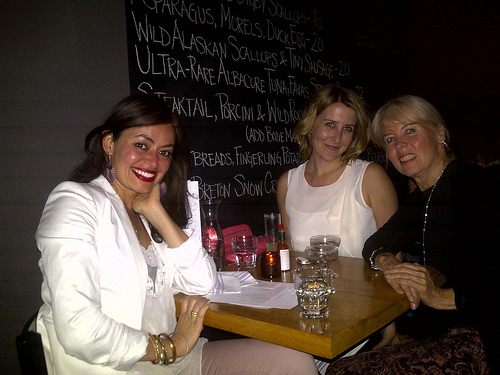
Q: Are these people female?
A: Yes, all the people are female.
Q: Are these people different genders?
A: No, all the people are female.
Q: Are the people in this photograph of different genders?
A: No, all the people are female.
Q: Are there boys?
A: No, there are no boys.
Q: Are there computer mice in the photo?
A: No, there are no computer mice.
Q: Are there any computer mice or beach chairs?
A: No, there are no computer mice or beach chairs.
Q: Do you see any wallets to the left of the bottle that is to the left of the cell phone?
A: Yes, there is a wallet to the left of the bottle.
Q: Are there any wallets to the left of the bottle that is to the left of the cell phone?
A: Yes, there is a wallet to the left of the bottle.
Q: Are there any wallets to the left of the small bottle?
A: Yes, there is a wallet to the left of the bottle.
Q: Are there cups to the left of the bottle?
A: No, there is a wallet to the left of the bottle.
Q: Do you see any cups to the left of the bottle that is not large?
A: No, there is a wallet to the left of the bottle.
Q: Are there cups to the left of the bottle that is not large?
A: No, there is a wallet to the left of the bottle.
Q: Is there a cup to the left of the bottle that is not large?
A: No, there is a wallet to the left of the bottle.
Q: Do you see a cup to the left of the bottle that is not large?
A: No, there is a wallet to the left of the bottle.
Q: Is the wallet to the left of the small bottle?
A: Yes, the wallet is to the left of the bottle.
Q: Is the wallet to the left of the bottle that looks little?
A: Yes, the wallet is to the left of the bottle.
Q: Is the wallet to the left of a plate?
A: No, the wallet is to the left of the bottle.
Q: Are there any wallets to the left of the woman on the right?
A: Yes, there is a wallet to the left of the woman.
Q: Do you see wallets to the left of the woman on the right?
A: Yes, there is a wallet to the left of the woman.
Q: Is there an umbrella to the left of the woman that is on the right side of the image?
A: No, there is a wallet to the left of the woman.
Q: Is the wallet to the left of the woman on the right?
A: Yes, the wallet is to the left of the woman.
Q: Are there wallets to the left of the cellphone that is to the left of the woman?
A: Yes, there is a wallet to the left of the mobile phone.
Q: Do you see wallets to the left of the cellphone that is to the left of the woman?
A: Yes, there is a wallet to the left of the mobile phone.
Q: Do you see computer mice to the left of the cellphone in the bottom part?
A: No, there is a wallet to the left of the cell phone.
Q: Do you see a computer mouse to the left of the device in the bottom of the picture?
A: No, there is a wallet to the left of the cell phone.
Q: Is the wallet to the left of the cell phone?
A: Yes, the wallet is to the left of the cell phone.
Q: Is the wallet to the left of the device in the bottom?
A: Yes, the wallet is to the left of the cell phone.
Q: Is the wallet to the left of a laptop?
A: No, the wallet is to the left of the cell phone.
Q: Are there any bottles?
A: Yes, there is a bottle.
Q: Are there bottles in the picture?
A: Yes, there is a bottle.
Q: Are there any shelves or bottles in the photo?
A: Yes, there is a bottle.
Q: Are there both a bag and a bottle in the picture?
A: No, there is a bottle but no bags.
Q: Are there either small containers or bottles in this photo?
A: Yes, there is a small bottle.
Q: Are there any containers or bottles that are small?
A: Yes, the bottle is small.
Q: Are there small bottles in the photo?
A: Yes, there is a small bottle.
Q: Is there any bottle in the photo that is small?
A: Yes, there is a bottle that is small.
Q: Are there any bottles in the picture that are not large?
A: Yes, there is a small bottle.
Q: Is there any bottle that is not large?
A: Yes, there is a small bottle.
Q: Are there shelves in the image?
A: No, there are no shelves.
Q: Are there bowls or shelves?
A: No, there are no shelves or bowls.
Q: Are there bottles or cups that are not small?
A: No, there is a bottle but it is small.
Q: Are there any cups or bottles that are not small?
A: No, there is a bottle but it is small.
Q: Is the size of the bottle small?
A: Yes, the bottle is small.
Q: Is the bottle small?
A: Yes, the bottle is small.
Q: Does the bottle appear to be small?
A: Yes, the bottle is small.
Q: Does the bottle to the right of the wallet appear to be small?
A: Yes, the bottle is small.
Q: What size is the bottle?
A: The bottle is small.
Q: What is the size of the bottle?
A: The bottle is small.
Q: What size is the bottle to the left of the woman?
A: The bottle is small.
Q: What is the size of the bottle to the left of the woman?
A: The bottle is small.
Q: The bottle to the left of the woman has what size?
A: The bottle is small.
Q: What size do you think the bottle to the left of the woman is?
A: The bottle is small.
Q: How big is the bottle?
A: The bottle is small.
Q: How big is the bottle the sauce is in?
A: The bottle is small.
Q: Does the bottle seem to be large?
A: No, the bottle is small.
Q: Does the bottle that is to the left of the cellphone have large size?
A: No, the bottle is small.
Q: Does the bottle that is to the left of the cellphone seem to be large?
A: No, the bottle is small.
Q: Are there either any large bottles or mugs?
A: No, there is a bottle but it is small.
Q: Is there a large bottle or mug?
A: No, there is a bottle but it is small.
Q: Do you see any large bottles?
A: No, there is a bottle but it is small.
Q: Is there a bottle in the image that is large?
A: No, there is a bottle but it is small.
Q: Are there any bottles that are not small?
A: No, there is a bottle but it is small.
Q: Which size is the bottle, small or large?
A: The bottle is small.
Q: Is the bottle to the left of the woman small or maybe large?
A: The bottle is small.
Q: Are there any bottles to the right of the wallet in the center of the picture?
A: Yes, there is a bottle to the right of the wallet.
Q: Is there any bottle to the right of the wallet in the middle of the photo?
A: Yes, there is a bottle to the right of the wallet.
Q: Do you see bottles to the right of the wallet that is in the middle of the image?
A: Yes, there is a bottle to the right of the wallet.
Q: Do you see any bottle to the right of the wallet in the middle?
A: Yes, there is a bottle to the right of the wallet.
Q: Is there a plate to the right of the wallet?
A: No, there is a bottle to the right of the wallet.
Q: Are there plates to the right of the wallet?
A: No, there is a bottle to the right of the wallet.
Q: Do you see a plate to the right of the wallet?
A: No, there is a bottle to the right of the wallet.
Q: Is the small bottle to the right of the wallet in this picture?
A: Yes, the bottle is to the right of the wallet.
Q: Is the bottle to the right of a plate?
A: No, the bottle is to the right of the wallet.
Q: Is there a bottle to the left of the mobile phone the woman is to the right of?
A: Yes, there is a bottle to the left of the cellphone.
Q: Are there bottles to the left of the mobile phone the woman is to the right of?
A: Yes, there is a bottle to the left of the cellphone.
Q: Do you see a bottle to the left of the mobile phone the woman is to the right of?
A: Yes, there is a bottle to the left of the cellphone.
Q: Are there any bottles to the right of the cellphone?
A: No, the bottle is to the left of the cellphone.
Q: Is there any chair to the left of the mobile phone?
A: No, there is a bottle to the left of the mobile phone.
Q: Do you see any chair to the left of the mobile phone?
A: No, there is a bottle to the left of the mobile phone.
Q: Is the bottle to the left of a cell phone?
A: Yes, the bottle is to the left of a cell phone.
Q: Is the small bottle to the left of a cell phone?
A: Yes, the bottle is to the left of a cell phone.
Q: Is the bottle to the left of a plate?
A: No, the bottle is to the left of a cell phone.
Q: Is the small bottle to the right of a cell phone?
A: No, the bottle is to the left of a cell phone.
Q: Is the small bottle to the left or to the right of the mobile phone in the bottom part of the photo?
A: The bottle is to the left of the mobile phone.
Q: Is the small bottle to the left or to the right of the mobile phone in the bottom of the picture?
A: The bottle is to the left of the mobile phone.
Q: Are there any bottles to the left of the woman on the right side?
A: Yes, there is a bottle to the left of the woman.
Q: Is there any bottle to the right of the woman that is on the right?
A: No, the bottle is to the left of the woman.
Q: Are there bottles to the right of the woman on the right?
A: No, the bottle is to the left of the woman.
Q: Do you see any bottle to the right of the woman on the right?
A: No, the bottle is to the left of the woman.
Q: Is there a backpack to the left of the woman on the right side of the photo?
A: No, there is a bottle to the left of the woman.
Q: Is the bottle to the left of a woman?
A: Yes, the bottle is to the left of a woman.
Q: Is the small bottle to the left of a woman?
A: Yes, the bottle is to the left of a woman.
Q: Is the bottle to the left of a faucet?
A: No, the bottle is to the left of a woman.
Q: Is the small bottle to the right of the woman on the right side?
A: No, the bottle is to the left of the woman.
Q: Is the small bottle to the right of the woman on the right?
A: No, the bottle is to the left of the woman.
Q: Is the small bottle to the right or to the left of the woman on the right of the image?
A: The bottle is to the left of the woman.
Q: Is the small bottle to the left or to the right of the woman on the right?
A: The bottle is to the left of the woman.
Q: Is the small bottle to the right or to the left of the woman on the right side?
A: The bottle is to the left of the woman.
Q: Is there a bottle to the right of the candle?
A: Yes, there is a bottle to the right of the candle.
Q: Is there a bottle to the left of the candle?
A: No, the bottle is to the right of the candle.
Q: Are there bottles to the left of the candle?
A: No, the bottle is to the right of the candle.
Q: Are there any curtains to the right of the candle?
A: No, there is a bottle to the right of the candle.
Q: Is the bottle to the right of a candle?
A: Yes, the bottle is to the right of a candle.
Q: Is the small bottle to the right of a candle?
A: Yes, the bottle is to the right of a candle.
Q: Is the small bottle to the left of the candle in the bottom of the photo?
A: No, the bottle is to the right of the candle.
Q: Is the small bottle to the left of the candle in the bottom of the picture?
A: No, the bottle is to the right of the candle.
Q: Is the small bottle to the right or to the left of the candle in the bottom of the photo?
A: The bottle is to the right of the candle.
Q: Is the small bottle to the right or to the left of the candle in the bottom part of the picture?
A: The bottle is to the right of the candle.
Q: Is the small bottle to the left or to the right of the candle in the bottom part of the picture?
A: The bottle is to the right of the candle.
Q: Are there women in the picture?
A: Yes, there is a woman.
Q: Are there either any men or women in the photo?
A: Yes, there is a woman.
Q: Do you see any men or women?
A: Yes, there is a woman.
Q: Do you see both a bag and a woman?
A: No, there is a woman but no bags.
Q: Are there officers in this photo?
A: No, there are no officers.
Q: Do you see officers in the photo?
A: No, there are no officers.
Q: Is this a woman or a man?
A: This is a woman.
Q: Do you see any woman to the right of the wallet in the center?
A: Yes, there is a woman to the right of the wallet.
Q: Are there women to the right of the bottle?
A: Yes, there is a woman to the right of the bottle.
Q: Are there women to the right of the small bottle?
A: Yes, there is a woman to the right of the bottle.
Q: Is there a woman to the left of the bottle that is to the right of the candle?
A: No, the woman is to the right of the bottle.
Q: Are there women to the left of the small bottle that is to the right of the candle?
A: No, the woman is to the right of the bottle.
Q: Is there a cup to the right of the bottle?
A: No, there is a woman to the right of the bottle.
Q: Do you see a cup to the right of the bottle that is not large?
A: No, there is a woman to the right of the bottle.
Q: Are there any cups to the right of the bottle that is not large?
A: No, there is a woman to the right of the bottle.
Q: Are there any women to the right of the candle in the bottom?
A: Yes, there is a woman to the right of the candle.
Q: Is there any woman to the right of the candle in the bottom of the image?
A: Yes, there is a woman to the right of the candle.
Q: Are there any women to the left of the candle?
A: No, the woman is to the right of the candle.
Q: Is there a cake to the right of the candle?
A: No, there is a woman to the right of the candle.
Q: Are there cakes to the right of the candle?
A: No, there is a woman to the right of the candle.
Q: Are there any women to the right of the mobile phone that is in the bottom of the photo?
A: Yes, there is a woman to the right of the cell phone.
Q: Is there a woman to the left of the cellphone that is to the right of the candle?
A: No, the woman is to the right of the mobile phone.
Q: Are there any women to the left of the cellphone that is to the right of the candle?
A: No, the woman is to the right of the mobile phone.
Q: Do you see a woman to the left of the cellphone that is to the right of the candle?
A: No, the woman is to the right of the mobile phone.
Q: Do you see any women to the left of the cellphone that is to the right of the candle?
A: No, the woman is to the right of the mobile phone.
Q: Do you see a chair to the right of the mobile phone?
A: No, there is a woman to the right of the mobile phone.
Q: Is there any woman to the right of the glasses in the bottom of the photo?
A: Yes, there is a woman to the right of the glasses.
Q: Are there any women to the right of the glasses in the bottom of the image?
A: Yes, there is a woman to the right of the glasses.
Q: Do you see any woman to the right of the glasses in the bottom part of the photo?
A: Yes, there is a woman to the right of the glasses.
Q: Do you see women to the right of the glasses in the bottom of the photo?
A: Yes, there is a woman to the right of the glasses.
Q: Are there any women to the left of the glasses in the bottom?
A: No, the woman is to the right of the glasses.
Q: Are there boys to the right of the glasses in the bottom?
A: No, there is a woman to the right of the glasses.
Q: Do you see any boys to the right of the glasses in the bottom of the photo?
A: No, there is a woman to the right of the glasses.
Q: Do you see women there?
A: Yes, there is a woman.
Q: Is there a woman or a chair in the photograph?
A: Yes, there is a woman.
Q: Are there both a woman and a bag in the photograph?
A: No, there is a woman but no bags.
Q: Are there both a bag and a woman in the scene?
A: No, there is a woman but no bags.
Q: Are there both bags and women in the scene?
A: No, there is a woman but no bags.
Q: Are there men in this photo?
A: No, there are no men.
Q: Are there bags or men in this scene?
A: No, there are no men or bags.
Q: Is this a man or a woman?
A: This is a woman.